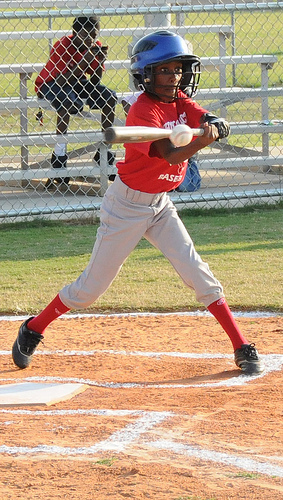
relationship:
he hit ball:
[12, 27, 261, 374] [169, 122, 192, 146]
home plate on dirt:
[0, 375, 93, 413] [89, 346, 148, 391]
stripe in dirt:
[0, 345, 280, 368] [0, 307, 281, 498]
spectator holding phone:
[34, 15, 116, 184] [84, 44, 107, 59]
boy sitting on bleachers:
[34, 14, 115, 180] [0, 5, 283, 176]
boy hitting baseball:
[28, 34, 264, 372] [167, 119, 194, 152]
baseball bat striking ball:
[99, 121, 218, 149] [169, 124, 192, 148]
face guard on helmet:
[140, 56, 200, 102] [114, 21, 198, 96]